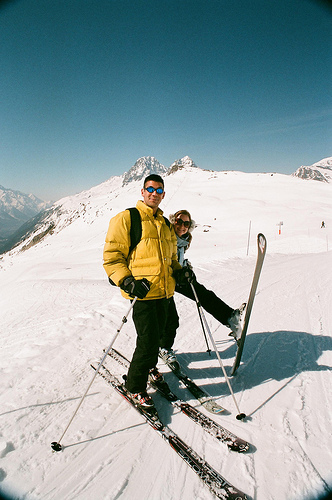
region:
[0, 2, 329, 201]
azure winter mountain sky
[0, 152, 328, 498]
two skiers posing for a photo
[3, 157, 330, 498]
two skiers on snowy mountainside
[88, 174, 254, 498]
male skier in ywllow parka and black pants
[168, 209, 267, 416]
woman in black ski pants with K2 skis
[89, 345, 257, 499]
pair of downhill snow skis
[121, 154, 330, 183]
rocky outcrops on top of ski mountain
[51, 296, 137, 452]
aluminum ski pole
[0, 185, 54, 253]
snow covered mountain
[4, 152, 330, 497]
two skiers on high mountain ski run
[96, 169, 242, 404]
a man and a woman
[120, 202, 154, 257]
black strap around the shoulder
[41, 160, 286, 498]
two people skiing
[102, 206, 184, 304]
bright yellow puffy jacket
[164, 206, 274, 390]
woman with her foot in the air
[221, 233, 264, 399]
ski on the foot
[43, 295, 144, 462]
long and skinny ski pole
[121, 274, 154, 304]
hand around the handle of the pole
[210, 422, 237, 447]
snow on the ski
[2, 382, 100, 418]
shadow in the snow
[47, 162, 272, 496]
A man and woman skier's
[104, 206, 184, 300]
A bright yellow ski jacket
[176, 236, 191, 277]
A light blue jacket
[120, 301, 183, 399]
A pair of black pants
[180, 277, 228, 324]
A dark colored pair of pants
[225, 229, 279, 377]
A woman with ski sticking upright in snow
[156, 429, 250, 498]
Black or brown ski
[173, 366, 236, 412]
A light colored ski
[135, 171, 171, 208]
A pair of sunglasses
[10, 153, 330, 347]
A mountain slope of white snow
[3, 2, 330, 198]
blue of daytime sky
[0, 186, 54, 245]
haze of mountain on horizon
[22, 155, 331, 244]
snow on rocky terrain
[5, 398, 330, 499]
ski marks in snow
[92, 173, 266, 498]
two people standing on skis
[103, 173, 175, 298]
yellow coat on man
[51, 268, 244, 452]
two poles in hands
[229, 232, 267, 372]
vertical ski in snow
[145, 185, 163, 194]
goggles with blue reflection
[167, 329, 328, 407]
shadow of skiers on snow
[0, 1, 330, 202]
A clear blue sky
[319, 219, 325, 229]
A person walking in the snow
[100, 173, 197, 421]
a man in a yellow jacket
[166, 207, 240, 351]
A woman in a blue jacket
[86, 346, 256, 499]
a pair of skis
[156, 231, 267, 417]
a pair of skis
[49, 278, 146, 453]
A metal ski pole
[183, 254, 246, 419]
A metal ski pole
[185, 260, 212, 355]
A metal ski pole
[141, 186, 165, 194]
a pair of sunglasses